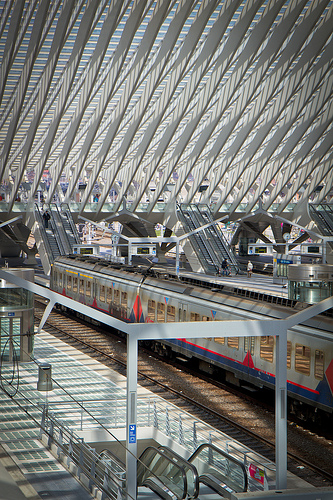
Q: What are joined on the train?
A: Cars.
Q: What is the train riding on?
A: Tracks.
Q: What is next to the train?
A: Gravel.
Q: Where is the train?
A: A subway stop.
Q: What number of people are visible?
A: Zero.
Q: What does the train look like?
A: Silver, red, and blue.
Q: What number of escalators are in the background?
A: Three.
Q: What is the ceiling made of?
A: Metal.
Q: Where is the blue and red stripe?
A: On the train.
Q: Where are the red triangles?
A: On the train.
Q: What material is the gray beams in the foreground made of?
A: Metal.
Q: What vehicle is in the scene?
A: Train.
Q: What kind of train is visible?
A: Passenger.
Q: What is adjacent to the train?
A: Tracks.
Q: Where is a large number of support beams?
A: From wall to ceiling.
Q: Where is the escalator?
A: Far end of terminal.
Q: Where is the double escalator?
A: Along the far wall.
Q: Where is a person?
A: On the center escalators.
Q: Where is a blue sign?
A: Beam in center of foreground.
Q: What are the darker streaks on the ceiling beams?
A: Shadows.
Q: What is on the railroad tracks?
A: Train.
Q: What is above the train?
A: Steel beams.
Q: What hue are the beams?
A: Silver.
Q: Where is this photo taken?
A: Train station.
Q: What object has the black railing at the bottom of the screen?
A: Escalator.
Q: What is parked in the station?
A: Train.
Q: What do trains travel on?
A: Tracks.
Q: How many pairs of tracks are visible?
A: Two.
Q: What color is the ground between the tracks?
A: Brown.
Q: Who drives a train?
A: Conductor.